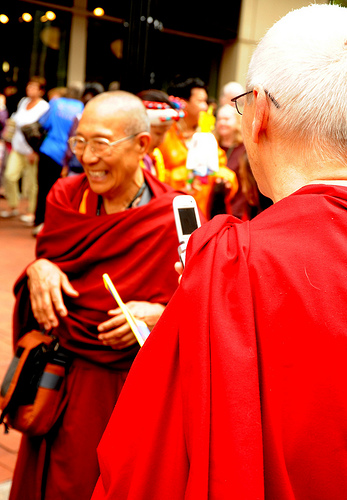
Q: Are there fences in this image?
A: No, there are no fences.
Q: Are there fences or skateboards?
A: No, there are no fences or skateboards.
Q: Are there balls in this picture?
A: No, there are no balls.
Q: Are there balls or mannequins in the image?
A: No, there are no balls or mannequins.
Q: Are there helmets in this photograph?
A: No, there are no helmets.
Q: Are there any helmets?
A: No, there are no helmets.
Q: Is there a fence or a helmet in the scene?
A: No, there are no helmets or fences.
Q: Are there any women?
A: Yes, there is a woman.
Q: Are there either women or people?
A: Yes, there is a woman.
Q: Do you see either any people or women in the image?
A: Yes, there is a woman.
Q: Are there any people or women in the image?
A: Yes, there is a woman.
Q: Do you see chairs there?
A: No, there are no chairs.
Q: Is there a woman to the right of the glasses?
A: Yes, there is a woman to the right of the glasses.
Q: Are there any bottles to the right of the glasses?
A: No, there is a woman to the right of the glasses.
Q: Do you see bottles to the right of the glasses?
A: No, there is a woman to the right of the glasses.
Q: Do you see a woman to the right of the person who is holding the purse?
A: Yes, there is a woman to the right of the person.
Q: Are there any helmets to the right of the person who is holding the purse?
A: No, there is a woman to the right of the person.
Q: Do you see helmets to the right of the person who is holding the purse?
A: No, there is a woman to the right of the person.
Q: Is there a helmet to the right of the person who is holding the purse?
A: No, there is a woman to the right of the person.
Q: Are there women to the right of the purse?
A: Yes, there is a woman to the right of the purse.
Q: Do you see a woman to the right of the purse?
A: Yes, there is a woman to the right of the purse.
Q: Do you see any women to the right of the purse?
A: Yes, there is a woman to the right of the purse.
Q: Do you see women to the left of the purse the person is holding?
A: No, the woman is to the right of the purse.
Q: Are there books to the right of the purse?
A: No, there is a woman to the right of the purse.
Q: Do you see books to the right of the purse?
A: No, there is a woman to the right of the purse.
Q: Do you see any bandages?
A: No, there are no bandages.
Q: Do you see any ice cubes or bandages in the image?
A: No, there are no bandages or ice cubes.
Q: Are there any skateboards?
A: No, there are no skateboards.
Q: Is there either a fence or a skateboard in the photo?
A: No, there are no skateboards or fences.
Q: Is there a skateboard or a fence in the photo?
A: No, there are no skateboards or fences.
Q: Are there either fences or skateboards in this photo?
A: No, there are no skateboards or fences.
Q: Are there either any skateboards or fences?
A: No, there are no skateboards or fences.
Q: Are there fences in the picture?
A: No, there are no fences.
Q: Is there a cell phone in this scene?
A: Yes, there is a cell phone.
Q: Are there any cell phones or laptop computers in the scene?
A: Yes, there is a cell phone.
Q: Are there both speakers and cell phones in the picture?
A: No, there is a cell phone but no speakers.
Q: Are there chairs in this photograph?
A: No, there are no chairs.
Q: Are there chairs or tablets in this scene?
A: No, there are no chairs or tablets.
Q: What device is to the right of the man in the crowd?
A: The device is a cell phone.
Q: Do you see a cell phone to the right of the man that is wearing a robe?
A: Yes, there is a cell phone to the right of the man.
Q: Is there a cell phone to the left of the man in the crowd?
A: No, the cell phone is to the right of the man.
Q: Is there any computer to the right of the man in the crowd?
A: No, there is a cell phone to the right of the man.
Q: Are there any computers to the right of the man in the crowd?
A: No, there is a cell phone to the right of the man.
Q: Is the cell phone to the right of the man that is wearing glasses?
A: Yes, the cell phone is to the right of the man.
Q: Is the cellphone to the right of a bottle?
A: No, the cellphone is to the right of the man.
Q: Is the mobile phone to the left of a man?
A: No, the mobile phone is to the right of a man.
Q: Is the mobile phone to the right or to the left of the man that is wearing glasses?
A: The mobile phone is to the right of the man.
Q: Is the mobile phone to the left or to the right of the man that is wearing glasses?
A: The mobile phone is to the right of the man.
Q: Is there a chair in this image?
A: No, there are no chairs.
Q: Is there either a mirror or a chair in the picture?
A: No, there are no chairs or mirrors.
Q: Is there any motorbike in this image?
A: No, there are no motorcycles.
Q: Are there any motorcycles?
A: No, there are no motorcycles.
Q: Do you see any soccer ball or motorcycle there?
A: No, there are no motorcycles or soccer balls.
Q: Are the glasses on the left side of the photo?
A: Yes, the glasses are on the left of the image.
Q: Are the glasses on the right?
A: No, the glasses are on the left of the image.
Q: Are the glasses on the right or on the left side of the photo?
A: The glasses are on the left of the image.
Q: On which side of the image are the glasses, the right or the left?
A: The glasses are on the left of the image.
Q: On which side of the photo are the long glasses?
A: The glasses are on the left of the image.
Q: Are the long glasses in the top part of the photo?
A: Yes, the glasses are in the top of the image.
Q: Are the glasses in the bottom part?
A: No, the glasses are in the top of the image.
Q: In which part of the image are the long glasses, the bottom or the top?
A: The glasses are in the top of the image.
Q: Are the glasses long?
A: Yes, the glasses are long.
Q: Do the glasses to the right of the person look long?
A: Yes, the glasses are long.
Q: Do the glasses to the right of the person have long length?
A: Yes, the glasses are long.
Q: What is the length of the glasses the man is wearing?
A: The glasses are long.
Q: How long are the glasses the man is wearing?
A: The glasses are long.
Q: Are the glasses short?
A: No, the glasses are long.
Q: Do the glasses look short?
A: No, the glasses are long.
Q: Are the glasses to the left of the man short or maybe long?
A: The glasses are long.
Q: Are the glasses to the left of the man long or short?
A: The glasses are long.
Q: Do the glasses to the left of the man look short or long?
A: The glasses are long.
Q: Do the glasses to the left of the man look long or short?
A: The glasses are long.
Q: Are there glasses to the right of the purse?
A: Yes, there are glasses to the right of the purse.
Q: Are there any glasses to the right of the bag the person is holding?
A: Yes, there are glasses to the right of the purse.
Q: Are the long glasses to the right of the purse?
A: Yes, the glasses are to the right of the purse.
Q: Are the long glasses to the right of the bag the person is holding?
A: Yes, the glasses are to the right of the purse.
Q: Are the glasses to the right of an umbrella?
A: No, the glasses are to the right of the purse.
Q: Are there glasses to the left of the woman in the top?
A: Yes, there are glasses to the left of the woman.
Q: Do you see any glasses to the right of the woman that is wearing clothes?
A: No, the glasses are to the left of the woman.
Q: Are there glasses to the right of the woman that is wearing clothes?
A: No, the glasses are to the left of the woman.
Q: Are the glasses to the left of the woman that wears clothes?
A: Yes, the glasses are to the left of the woman.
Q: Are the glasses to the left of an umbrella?
A: No, the glasses are to the left of the woman.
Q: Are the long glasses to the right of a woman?
A: No, the glasses are to the left of a woman.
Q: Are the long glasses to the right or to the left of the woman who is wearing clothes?
A: The glasses are to the left of the woman.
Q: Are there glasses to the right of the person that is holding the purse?
A: Yes, there are glasses to the right of the person.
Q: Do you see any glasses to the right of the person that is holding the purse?
A: Yes, there are glasses to the right of the person.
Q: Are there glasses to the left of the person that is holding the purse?
A: No, the glasses are to the right of the person.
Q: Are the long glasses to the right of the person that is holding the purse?
A: Yes, the glasses are to the right of the person.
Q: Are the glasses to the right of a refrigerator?
A: No, the glasses are to the right of the person.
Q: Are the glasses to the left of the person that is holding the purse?
A: No, the glasses are to the right of the person.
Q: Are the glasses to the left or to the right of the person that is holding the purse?
A: The glasses are to the right of the person.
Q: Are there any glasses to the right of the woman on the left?
A: Yes, there are glasses to the right of the woman.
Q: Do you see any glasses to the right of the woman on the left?
A: Yes, there are glasses to the right of the woman.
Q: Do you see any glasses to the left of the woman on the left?
A: No, the glasses are to the right of the woman.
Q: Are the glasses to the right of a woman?
A: Yes, the glasses are to the right of a woman.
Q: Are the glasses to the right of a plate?
A: No, the glasses are to the right of a woman.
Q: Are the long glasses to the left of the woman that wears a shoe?
A: No, the glasses are to the right of the woman.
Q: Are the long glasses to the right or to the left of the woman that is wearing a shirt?
A: The glasses are to the right of the woman.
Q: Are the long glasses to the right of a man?
A: No, the glasses are to the left of a man.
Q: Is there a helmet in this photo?
A: No, there are no helmets.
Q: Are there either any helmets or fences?
A: No, there are no helmets or fences.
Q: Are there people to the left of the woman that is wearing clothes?
A: Yes, there is a person to the left of the woman.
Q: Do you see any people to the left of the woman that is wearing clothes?
A: Yes, there is a person to the left of the woman.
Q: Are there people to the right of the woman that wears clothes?
A: No, the person is to the left of the woman.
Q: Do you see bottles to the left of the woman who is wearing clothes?
A: No, there is a person to the left of the woman.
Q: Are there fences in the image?
A: No, there are no fences.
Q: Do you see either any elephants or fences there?
A: No, there are no fences or elephants.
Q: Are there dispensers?
A: No, there are no dispensers.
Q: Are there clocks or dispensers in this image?
A: No, there are no dispensers or clocks.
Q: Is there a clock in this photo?
A: No, there are no clocks.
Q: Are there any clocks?
A: No, there are no clocks.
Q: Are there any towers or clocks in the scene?
A: No, there are no clocks or towers.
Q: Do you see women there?
A: Yes, there is a woman.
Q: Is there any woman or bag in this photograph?
A: Yes, there is a woman.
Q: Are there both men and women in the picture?
A: Yes, there are both a woman and a man.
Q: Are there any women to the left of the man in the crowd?
A: Yes, there is a woman to the left of the man.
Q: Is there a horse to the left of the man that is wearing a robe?
A: No, there is a woman to the left of the man.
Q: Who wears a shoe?
A: The woman wears a shoe.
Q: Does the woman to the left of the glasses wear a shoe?
A: Yes, the woman wears a shoe.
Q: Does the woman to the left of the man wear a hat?
A: No, the woman wears a shoe.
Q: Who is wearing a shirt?
A: The woman is wearing a shirt.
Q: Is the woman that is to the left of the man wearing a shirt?
A: Yes, the woman is wearing a shirt.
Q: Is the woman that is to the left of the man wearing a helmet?
A: No, the woman is wearing a shirt.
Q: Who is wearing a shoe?
A: The woman is wearing a shoe.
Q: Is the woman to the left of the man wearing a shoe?
A: Yes, the woman is wearing a shoe.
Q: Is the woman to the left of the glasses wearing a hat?
A: No, the woman is wearing a shoe.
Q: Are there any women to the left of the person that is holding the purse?
A: Yes, there is a woman to the left of the person.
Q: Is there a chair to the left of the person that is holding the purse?
A: No, there is a woman to the left of the person.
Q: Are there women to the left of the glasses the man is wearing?
A: Yes, there is a woman to the left of the glasses.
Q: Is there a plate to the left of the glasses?
A: No, there is a woman to the left of the glasses.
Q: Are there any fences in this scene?
A: No, there are no fences.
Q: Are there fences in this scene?
A: No, there are no fences.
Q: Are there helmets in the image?
A: No, there are no helmets.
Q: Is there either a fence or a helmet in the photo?
A: No, there are no helmets or fences.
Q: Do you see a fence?
A: No, there are no fences.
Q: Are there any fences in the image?
A: No, there are no fences.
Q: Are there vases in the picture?
A: No, there are no vases.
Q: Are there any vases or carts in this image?
A: No, there are no vases or carts.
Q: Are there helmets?
A: No, there are no helmets.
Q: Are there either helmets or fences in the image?
A: No, there are no helmets or fences.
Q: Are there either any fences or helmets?
A: No, there are no helmets or fences.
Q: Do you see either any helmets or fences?
A: No, there are no helmets or fences.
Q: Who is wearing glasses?
A: The man is wearing glasses.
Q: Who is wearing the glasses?
A: The man is wearing glasses.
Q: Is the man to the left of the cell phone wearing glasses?
A: Yes, the man is wearing glasses.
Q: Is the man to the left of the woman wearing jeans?
A: No, the man is wearing glasses.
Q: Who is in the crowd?
A: The man is in the crowd.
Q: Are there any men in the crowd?
A: Yes, there is a man in the crowd.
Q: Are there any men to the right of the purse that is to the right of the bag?
A: Yes, there is a man to the right of the purse.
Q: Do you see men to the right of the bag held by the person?
A: Yes, there is a man to the right of the purse.